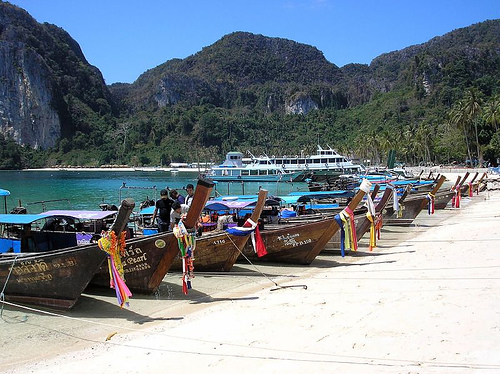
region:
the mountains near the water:
[0, 0, 499, 228]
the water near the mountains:
[1, 0, 499, 230]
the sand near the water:
[0, 169, 499, 372]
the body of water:
[0, 168, 326, 228]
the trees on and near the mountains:
[1, 0, 497, 170]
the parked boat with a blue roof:
[0, 187, 136, 311]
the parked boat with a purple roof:
[38, 179, 215, 294]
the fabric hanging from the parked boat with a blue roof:
[0, 185, 135, 311]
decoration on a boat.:
[101, 240, 141, 297]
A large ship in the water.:
[199, 137, 361, 186]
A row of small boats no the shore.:
[26, 188, 389, 314]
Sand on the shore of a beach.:
[51, 317, 481, 372]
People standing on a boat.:
[150, 184, 210, 241]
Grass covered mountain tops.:
[6, 10, 498, 82]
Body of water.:
[17, 169, 169, 203]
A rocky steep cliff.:
[4, 45, 73, 160]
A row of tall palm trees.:
[356, 99, 493, 164]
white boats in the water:
[207, 146, 350, 183]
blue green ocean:
[5, 168, 344, 223]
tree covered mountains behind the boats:
[1, 1, 498, 134]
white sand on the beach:
[2, 168, 499, 368]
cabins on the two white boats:
[212, 150, 342, 173]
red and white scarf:
[242, 213, 267, 254]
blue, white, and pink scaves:
[338, 203, 358, 251]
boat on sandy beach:
[0, 197, 136, 323]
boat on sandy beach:
[99, 178, 214, 298]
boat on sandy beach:
[171, 187, 267, 269]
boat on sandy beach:
[256, 182, 370, 264]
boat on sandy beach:
[317, 187, 393, 257]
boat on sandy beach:
[387, 178, 444, 225]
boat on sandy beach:
[434, 172, 467, 209]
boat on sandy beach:
[463, 171, 486, 194]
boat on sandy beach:
[383, 183, 409, 230]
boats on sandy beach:
[3, 170, 489, 308]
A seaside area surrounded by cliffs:
[0, 0, 499, 372]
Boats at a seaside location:
[2, 143, 485, 310]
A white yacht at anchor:
[210, 143, 365, 192]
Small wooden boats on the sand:
[1, 170, 480, 306]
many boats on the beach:
[3, 153, 459, 366]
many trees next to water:
[141, 50, 309, 129]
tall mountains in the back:
[3, 3, 496, 168]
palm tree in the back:
[445, 87, 480, 159]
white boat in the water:
[175, 140, 380, 180]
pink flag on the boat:
[110, 255, 130, 296]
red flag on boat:
[250, 221, 265, 256]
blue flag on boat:
[330, 210, 341, 256]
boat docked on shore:
[15, 185, 125, 330]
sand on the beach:
[25, 155, 495, 370]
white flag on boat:
[353, 175, 378, 216]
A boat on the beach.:
[1, 247, 122, 330]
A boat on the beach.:
[148, 213, 272, 268]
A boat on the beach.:
[206, 207, 361, 267]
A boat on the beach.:
[230, 207, 383, 256]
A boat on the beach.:
[233, 185, 411, 227]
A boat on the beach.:
[243, 184, 408, 239]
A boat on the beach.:
[264, 191, 441, 220]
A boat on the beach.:
[318, 192, 468, 215]